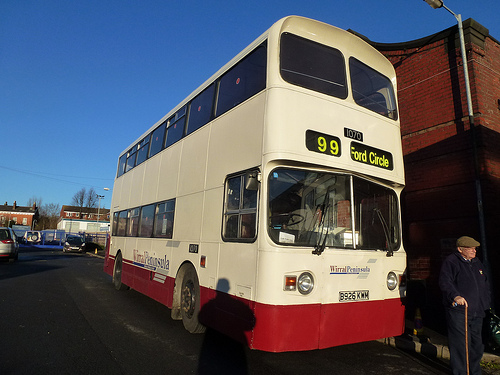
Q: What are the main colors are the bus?
A: Red and white.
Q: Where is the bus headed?
A: 99 Ford Circle.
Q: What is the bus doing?
A: Stopped.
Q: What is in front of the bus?
A: Older man.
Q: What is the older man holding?
A: A cane.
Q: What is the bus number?
A: 1070.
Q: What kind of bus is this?
A: Double decker.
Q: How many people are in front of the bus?
A: One.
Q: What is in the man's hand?
A: A cane.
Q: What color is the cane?
A: Brown.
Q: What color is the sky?
A: Blue.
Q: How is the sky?
A: Clear and bright.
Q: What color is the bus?
A: White and red.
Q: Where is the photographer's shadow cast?
A: On the bus.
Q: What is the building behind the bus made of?
A: Brick.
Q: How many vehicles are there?
A: Four.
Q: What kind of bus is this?
A: Double decker.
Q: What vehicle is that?
A: A bus.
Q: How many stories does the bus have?
A: Two.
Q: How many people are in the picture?
A: One.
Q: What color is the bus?
A: White and red.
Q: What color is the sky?
A: Blue.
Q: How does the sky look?
A: Clear.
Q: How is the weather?
A: Sunny.